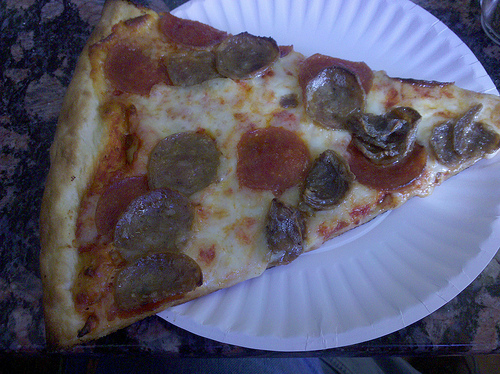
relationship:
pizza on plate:
[105, 48, 350, 205] [113, 3, 496, 351]